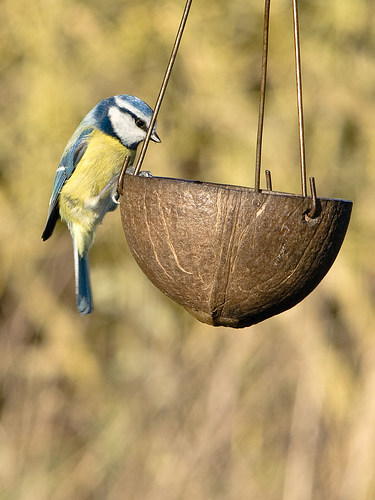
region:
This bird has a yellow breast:
[75, 162, 105, 248]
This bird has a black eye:
[138, 111, 146, 137]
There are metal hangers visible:
[240, 61, 273, 147]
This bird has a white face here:
[120, 121, 131, 159]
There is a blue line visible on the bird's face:
[122, 101, 125, 114]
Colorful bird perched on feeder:
[41, 93, 164, 315]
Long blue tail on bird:
[72, 250, 93, 315]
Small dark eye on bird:
[134, 118, 146, 128]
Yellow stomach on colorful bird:
[58, 125, 137, 227]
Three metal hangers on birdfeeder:
[114, 2, 324, 220]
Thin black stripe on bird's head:
[113, 101, 148, 131]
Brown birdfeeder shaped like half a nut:
[116, 3, 356, 331]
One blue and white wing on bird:
[38, 125, 94, 242]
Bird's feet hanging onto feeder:
[110, 163, 153, 205]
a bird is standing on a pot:
[50, 71, 327, 287]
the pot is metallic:
[130, 107, 344, 298]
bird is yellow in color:
[76, 143, 133, 214]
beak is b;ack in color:
[143, 122, 162, 140]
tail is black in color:
[63, 244, 109, 316]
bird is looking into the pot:
[79, 73, 182, 207]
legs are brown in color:
[98, 165, 136, 203]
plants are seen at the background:
[39, 302, 145, 405]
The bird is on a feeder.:
[40, 1, 352, 329]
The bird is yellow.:
[88, 146, 112, 173]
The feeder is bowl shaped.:
[121, 173, 350, 327]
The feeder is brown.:
[181, 209, 283, 282]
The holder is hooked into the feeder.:
[304, 177, 320, 217]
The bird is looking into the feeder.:
[128, 112, 148, 131]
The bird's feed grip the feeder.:
[110, 188, 123, 207]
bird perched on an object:
[40, 88, 160, 314]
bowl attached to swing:
[125, 164, 344, 329]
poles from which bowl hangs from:
[151, 5, 320, 176]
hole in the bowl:
[303, 203, 324, 225]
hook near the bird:
[115, 155, 132, 189]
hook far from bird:
[298, 172, 322, 214]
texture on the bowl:
[140, 197, 295, 280]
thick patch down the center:
[211, 195, 236, 315]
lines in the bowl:
[293, 234, 322, 289]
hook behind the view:
[263, 168, 277, 191]